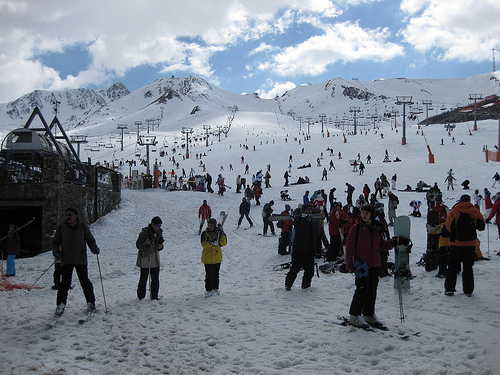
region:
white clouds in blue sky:
[3, 11, 50, 51]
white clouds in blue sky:
[90, 19, 130, 41]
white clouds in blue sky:
[204, 9, 242, 50]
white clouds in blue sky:
[273, 36, 328, 66]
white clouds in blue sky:
[326, 26, 406, 71]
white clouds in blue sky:
[390, 13, 433, 63]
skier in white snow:
[130, 210, 170, 297]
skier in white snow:
[40, 190, 111, 336]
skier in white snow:
[276, 191, 321, 286]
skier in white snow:
[339, 204, 413, 345]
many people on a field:
[8, 100, 489, 350]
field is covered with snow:
[23, 131, 498, 373]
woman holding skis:
[194, 205, 232, 300]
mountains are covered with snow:
[8, 65, 459, 130]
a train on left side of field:
[0, 106, 208, 286]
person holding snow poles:
[23, 203, 120, 324]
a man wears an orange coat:
[439, 187, 494, 305]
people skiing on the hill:
[161, 103, 381, 165]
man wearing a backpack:
[439, 190, 486, 298]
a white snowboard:
[388, 208, 415, 303]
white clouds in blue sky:
[22, 6, 76, 44]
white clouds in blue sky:
[139, 2, 210, 61]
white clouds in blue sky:
[233, 42, 261, 75]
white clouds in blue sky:
[267, 11, 313, 48]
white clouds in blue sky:
[359, 28, 390, 61]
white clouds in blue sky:
[425, 15, 450, 46]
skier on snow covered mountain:
[42, 200, 104, 320]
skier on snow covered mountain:
[133, 212, 183, 300]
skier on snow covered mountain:
[186, 208, 222, 293]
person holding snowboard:
[368, 195, 422, 304]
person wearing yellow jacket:
[199, 225, 234, 270]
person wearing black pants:
[344, 255, 386, 315]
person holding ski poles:
[26, 244, 123, 308]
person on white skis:
[23, 288, 110, 348]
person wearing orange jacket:
[435, 199, 485, 252]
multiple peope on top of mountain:
[83, 113, 493, 330]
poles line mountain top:
[58, 90, 253, 203]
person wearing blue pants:
[5, 248, 22, 279]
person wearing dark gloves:
[45, 243, 126, 264]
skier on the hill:
[191, 210, 230, 300]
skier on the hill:
[133, 210, 168, 302]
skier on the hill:
[39, 202, 99, 319]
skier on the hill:
[282, 200, 337, 305]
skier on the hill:
[342, 212, 384, 334]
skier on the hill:
[234, 195, 254, 231]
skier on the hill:
[196, 198, 211, 230]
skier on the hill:
[316, 165, 333, 182]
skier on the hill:
[443, 191, 486, 297]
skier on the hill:
[215, 171, 229, 198]